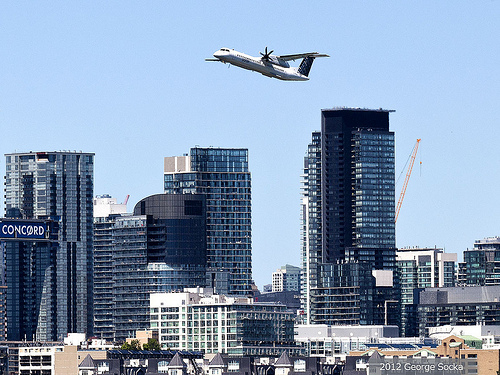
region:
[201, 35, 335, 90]
Airplane flying over city.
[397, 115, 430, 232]
Part of crane sticking out from side of building.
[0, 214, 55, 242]
Name of business across top of building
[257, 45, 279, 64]
Propeller in front of plane engine.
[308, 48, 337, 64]
Rear horizontal stabilizer on plane.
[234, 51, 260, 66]
Windows along side of plane.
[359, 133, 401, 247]
Windows along side of building.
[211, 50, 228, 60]
Nose cone of airplane.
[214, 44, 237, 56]
Windows over cockpit area of plane.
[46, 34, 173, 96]
Clear blue of sky.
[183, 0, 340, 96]
this is a plane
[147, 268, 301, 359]
this is a building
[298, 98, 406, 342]
this is a building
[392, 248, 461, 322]
this is a building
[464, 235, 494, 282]
this is a building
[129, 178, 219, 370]
this is a building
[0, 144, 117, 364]
this is a building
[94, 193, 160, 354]
this is a building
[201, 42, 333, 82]
Plane flying in the sky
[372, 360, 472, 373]
Photographer was George Socka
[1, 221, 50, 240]
Building belongs to the Concord company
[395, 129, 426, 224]
Crane behind skyscraper building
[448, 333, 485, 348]
Roof of building is green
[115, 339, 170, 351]
Trees located on top of building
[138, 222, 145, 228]
Chairs on baclony on top floor of building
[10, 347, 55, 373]
Parking deck of building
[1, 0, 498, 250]
Sky is clear with no clouds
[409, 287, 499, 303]
Roof of building is gray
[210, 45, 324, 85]
airplane flying over a city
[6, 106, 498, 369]
city with tall buildings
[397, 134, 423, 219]
a yellow construction crane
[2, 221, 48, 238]
a blue concord billboard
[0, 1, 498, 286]
clear blue sky over the city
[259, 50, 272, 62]
the airplane's propeller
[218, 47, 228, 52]
the plane's cockpit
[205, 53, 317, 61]
the airplane's wings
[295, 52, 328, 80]
the airplane's tail section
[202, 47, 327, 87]
white airplane with a blue tail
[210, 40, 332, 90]
large white plane in air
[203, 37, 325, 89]
large white commercial plane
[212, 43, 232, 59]
cockpit of plane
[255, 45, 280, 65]
black propeller on plane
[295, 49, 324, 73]
blue tail wing on plane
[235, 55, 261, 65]
row of windows on side of plane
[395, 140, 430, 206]
tall yellow crane in back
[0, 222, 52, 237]
white sign on building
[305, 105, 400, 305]
tall building in city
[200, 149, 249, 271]
windows on side of building